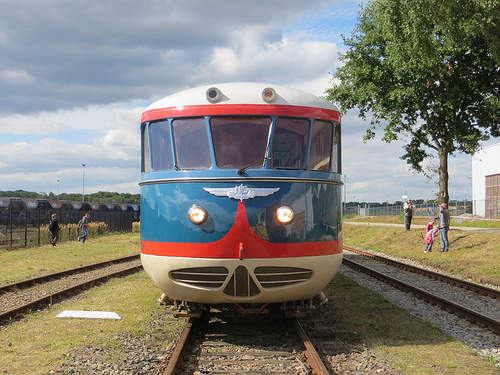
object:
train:
[140, 82, 344, 320]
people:
[426, 219, 435, 231]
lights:
[275, 205, 296, 225]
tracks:
[0, 257, 141, 304]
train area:
[0, 84, 499, 375]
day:
[0, 3, 498, 373]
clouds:
[279, 39, 339, 69]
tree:
[331, 3, 500, 230]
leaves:
[366, 129, 375, 140]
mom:
[437, 202, 452, 254]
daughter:
[424, 227, 440, 254]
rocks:
[41, 368, 57, 374]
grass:
[0, 317, 500, 375]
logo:
[201, 184, 280, 203]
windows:
[211, 115, 268, 170]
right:
[492, 2, 500, 375]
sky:
[0, 1, 334, 80]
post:
[78, 162, 87, 204]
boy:
[47, 213, 60, 246]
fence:
[0, 201, 140, 249]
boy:
[77, 213, 90, 244]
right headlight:
[276, 205, 295, 226]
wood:
[52, 307, 120, 319]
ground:
[3, 217, 500, 374]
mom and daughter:
[422, 201, 450, 255]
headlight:
[186, 205, 209, 225]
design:
[164, 262, 316, 303]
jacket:
[424, 229, 435, 244]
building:
[468, 140, 499, 222]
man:
[403, 198, 414, 231]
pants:
[404, 216, 411, 231]